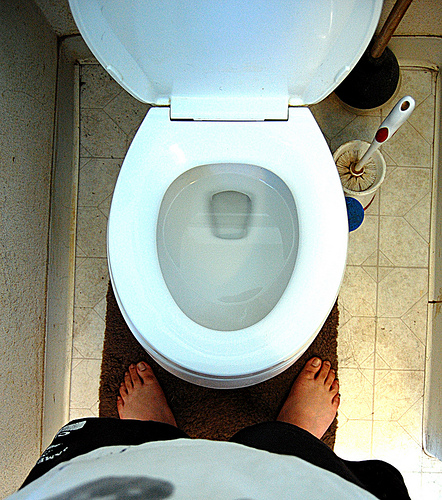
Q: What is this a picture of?
A: Someone standing over the toilet.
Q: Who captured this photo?
A: A photographer.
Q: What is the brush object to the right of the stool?
A: Toilet bowl brush.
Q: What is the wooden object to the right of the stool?
A: Plunger.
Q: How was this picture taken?
A: Camera.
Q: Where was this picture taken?
A: The bathroom.